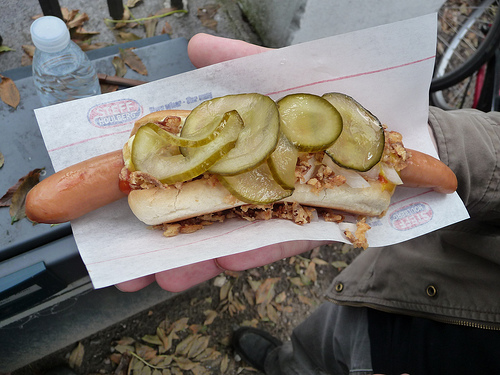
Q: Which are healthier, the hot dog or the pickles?
A: The pickles are healthier than the hot dog.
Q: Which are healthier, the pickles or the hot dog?
A: The pickles are healthier than the hot dog.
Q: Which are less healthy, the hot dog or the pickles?
A: The hot dog are less healthy than the pickles.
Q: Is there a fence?
A: No, there are no fences.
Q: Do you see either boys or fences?
A: No, there are no fences or boys.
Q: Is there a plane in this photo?
A: No, there are no airplanes.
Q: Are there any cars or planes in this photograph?
A: No, there are no planes or cars.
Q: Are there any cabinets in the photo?
A: No, there are no cabinets.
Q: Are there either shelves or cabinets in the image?
A: No, there are no cabinets or shelves.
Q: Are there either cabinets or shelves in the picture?
A: No, there are no cabinets or shelves.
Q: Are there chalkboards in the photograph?
A: No, there are no chalkboards.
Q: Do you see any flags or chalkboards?
A: No, there are no chalkboards or flags.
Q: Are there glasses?
A: No, there are no glasses.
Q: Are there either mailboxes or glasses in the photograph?
A: No, there are no glasses or mailboxes.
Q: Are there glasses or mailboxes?
A: No, there are no glasses or mailboxes.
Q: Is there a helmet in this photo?
A: No, there are no helmets.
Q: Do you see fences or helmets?
A: No, there are no helmets or fences.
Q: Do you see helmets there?
A: No, there are no helmets.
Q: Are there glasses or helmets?
A: No, there are no helmets or glasses.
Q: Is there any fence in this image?
A: No, there are no fences.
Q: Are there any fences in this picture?
A: No, there are no fences.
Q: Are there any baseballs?
A: No, there are no baseballs.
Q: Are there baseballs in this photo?
A: No, there are no baseballs.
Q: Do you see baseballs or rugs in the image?
A: No, there are no baseballs or rugs.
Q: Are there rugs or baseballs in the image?
A: No, there are no baseballs or rugs.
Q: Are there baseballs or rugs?
A: No, there are no baseballs or rugs.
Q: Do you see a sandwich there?
A: Yes, there is a sandwich.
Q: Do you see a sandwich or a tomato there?
A: Yes, there is a sandwich.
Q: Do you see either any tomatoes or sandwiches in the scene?
A: Yes, there is a sandwich.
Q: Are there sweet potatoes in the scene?
A: No, there are no sweet potatoes.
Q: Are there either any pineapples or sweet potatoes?
A: No, there are no sweet potatoes or pineapples.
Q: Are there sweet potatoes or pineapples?
A: No, there are no sweet potatoes or pineapples.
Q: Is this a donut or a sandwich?
A: This is a sandwich.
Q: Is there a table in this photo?
A: Yes, there is a table.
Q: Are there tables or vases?
A: Yes, there is a table.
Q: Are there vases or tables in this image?
A: Yes, there is a table.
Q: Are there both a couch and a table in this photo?
A: No, there is a table but no couches.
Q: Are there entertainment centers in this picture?
A: No, there are no entertainment centers.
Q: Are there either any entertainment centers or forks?
A: No, there are no entertainment centers or forks.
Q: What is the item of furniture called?
A: The piece of furniture is a table.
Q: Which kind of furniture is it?
A: The piece of furniture is a table.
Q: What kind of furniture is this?
A: This is a table.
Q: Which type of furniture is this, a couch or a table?
A: This is a table.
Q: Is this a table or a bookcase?
A: This is a table.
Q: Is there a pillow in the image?
A: No, there are no pillows.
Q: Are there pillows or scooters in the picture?
A: No, there are no pillows or scooters.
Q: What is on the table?
A: The water is on the table.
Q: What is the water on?
A: The water is on the table.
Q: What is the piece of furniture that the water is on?
A: The piece of furniture is a table.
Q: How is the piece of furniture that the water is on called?
A: The piece of furniture is a table.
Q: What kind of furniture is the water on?
A: The water is on the table.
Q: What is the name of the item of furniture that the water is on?
A: The piece of furniture is a table.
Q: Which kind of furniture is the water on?
A: The water is on the table.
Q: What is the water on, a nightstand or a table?
A: The water is on a table.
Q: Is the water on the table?
A: Yes, the water is on the table.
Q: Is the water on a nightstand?
A: No, the water is on the table.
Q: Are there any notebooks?
A: No, there are no notebooks.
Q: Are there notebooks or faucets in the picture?
A: No, there are no notebooks or faucets.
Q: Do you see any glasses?
A: No, there are no glasses.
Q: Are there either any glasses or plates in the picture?
A: No, there are no glasses or plates.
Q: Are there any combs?
A: No, there are no combs.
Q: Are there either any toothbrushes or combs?
A: No, there are no combs or toothbrushes.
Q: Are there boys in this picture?
A: No, there are no boys.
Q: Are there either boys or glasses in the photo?
A: No, there are no boys or glasses.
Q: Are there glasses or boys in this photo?
A: No, there are no boys or glasses.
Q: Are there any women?
A: No, there are no women.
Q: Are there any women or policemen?
A: No, there are no women or policemen.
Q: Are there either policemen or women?
A: No, there are no women or policemen.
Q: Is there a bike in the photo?
A: Yes, there is a bike.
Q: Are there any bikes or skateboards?
A: Yes, there is a bike.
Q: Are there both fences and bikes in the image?
A: No, there is a bike but no fences.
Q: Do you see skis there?
A: No, there are no skis.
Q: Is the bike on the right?
A: Yes, the bike is on the right of the image.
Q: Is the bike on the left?
A: No, the bike is on the right of the image.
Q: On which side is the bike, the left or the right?
A: The bike is on the right of the image.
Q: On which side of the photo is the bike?
A: The bike is on the right of the image.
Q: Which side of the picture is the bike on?
A: The bike is on the right of the image.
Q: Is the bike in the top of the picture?
A: Yes, the bike is in the top of the image.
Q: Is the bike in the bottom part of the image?
A: No, the bike is in the top of the image.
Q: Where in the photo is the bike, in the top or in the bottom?
A: The bike is in the top of the image.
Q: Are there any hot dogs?
A: Yes, there is a hot dog.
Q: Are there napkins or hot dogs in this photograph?
A: Yes, there is a hot dog.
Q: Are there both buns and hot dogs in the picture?
A: Yes, there are both a hot dog and a bun.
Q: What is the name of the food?
A: The food is a hot dog.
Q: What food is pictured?
A: The food is a hot dog.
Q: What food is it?
A: The food is a hot dog.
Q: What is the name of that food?
A: That is a hot dog.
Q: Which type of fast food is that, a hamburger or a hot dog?
A: That is a hot dog.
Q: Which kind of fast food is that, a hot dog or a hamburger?
A: That is a hot dog.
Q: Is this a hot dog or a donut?
A: This is a hot dog.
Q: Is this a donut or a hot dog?
A: This is a hot dog.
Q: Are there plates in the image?
A: No, there are no plates.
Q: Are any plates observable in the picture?
A: No, there are no plates.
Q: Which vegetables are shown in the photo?
A: The vegetables are pickles.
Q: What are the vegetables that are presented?
A: The vegetables are pickles.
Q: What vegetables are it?
A: The vegetables are pickles.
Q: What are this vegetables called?
A: These are pickles.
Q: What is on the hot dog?
A: The pickles are on the hot dog.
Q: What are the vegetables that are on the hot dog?
A: The vegetables are pickles.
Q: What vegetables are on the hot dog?
A: The vegetables are pickles.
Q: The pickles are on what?
A: The pickles are on the hot dog.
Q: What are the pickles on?
A: The pickles are on the hot dog.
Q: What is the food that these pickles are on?
A: The food is a hot dog.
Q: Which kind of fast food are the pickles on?
A: The pickles are on the hot dog.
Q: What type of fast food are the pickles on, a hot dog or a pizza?
A: The pickles are on a hot dog.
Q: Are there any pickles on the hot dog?
A: Yes, there are pickles on the hot dog.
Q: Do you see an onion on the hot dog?
A: No, there are pickles on the hot dog.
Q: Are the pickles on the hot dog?
A: Yes, the pickles are on the hot dog.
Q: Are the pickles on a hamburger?
A: No, the pickles are on the hot dog.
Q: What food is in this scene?
A: The food is a bun.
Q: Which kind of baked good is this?
A: This is a bun.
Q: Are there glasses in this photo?
A: No, there are no glasses.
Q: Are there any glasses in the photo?
A: No, there are no glasses.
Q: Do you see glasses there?
A: No, there are no glasses.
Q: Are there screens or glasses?
A: No, there are no glasses or screens.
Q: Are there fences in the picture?
A: No, there are no fences.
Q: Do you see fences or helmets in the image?
A: No, there are no fences or helmets.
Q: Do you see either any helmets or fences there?
A: No, there are no fences or helmets.